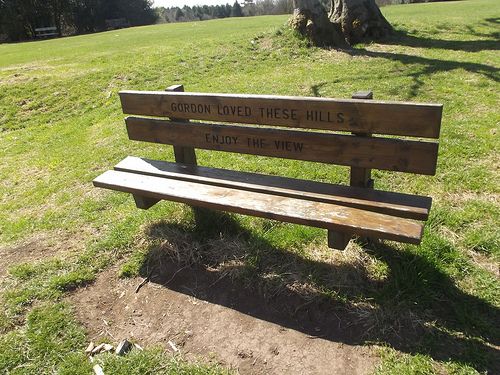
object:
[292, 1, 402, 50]
stump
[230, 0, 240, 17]
trees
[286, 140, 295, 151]
letter 'e'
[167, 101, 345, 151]
writing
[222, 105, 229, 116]
letter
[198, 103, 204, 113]
letter "o"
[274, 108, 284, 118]
"e"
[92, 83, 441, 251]
bench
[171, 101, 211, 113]
word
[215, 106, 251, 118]
word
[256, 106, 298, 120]
word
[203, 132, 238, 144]
word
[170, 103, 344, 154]
message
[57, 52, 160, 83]
grass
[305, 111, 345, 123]
words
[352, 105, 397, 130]
wood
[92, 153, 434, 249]
seat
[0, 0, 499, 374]
park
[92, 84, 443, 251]
wood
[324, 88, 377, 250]
support